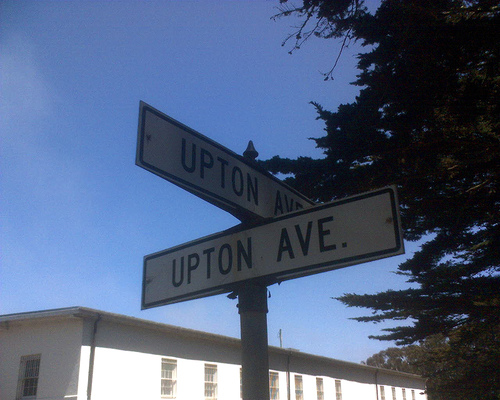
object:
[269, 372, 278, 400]
window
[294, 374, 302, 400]
window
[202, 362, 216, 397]
window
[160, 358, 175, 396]
window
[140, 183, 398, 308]
sign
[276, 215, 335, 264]
words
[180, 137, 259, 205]
words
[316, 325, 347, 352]
clouds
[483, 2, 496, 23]
leaves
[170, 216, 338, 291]
upton ave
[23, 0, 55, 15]
clouds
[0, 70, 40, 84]
cloud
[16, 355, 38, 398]
window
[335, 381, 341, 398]
window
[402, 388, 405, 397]
window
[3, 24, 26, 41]
cloud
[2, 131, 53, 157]
cloud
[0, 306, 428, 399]
building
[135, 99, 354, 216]
sign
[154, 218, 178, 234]
clouds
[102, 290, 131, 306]
clouds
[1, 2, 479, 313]
sky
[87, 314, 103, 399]
gutter drain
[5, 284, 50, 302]
clouds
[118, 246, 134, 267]
clouds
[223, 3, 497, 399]
trees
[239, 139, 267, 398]
pole